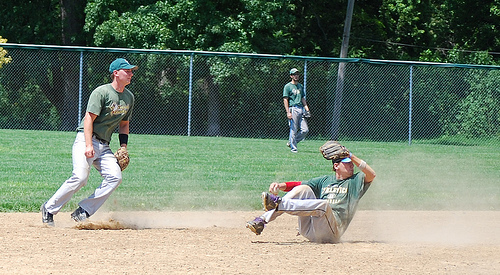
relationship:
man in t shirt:
[42, 57, 139, 225] [77, 85, 136, 139]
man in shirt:
[282, 68, 312, 152] [281, 82, 308, 108]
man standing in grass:
[282, 68, 312, 152] [1, 126, 500, 210]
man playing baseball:
[282, 68, 312, 152] [4, 5, 498, 273]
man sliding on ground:
[246, 142, 378, 246] [3, 206, 500, 274]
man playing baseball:
[246, 142, 378, 246] [4, 5, 498, 273]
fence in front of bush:
[1, 42, 500, 151] [410, 38, 500, 149]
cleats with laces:
[244, 216, 267, 234] [254, 214, 264, 226]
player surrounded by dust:
[246, 142, 378, 246] [367, 155, 499, 251]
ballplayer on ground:
[246, 142, 378, 246] [3, 206, 500, 274]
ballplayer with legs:
[246, 142, 378, 246] [247, 183, 333, 234]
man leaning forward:
[42, 57, 139, 225] [118, 60, 141, 238]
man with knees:
[42, 57, 139, 225] [69, 165, 129, 187]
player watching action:
[282, 68, 312, 152] [39, 58, 377, 245]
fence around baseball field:
[1, 42, 500, 151] [2, 125, 498, 273]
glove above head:
[317, 140, 351, 162] [332, 155, 357, 182]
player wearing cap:
[282, 68, 312, 152] [288, 66, 302, 74]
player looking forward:
[282, 68, 312, 152] [118, 60, 141, 238]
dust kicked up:
[367, 155, 499, 251] [329, 6, 481, 42]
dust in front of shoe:
[78, 213, 143, 233] [71, 207, 92, 224]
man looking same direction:
[246, 142, 378, 246] [395, 47, 478, 241]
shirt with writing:
[77, 85, 136, 139] [106, 101, 133, 117]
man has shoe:
[42, 57, 139, 225] [71, 207, 92, 224]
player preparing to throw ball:
[246, 142, 378, 246] [268, 182, 282, 196]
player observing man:
[282, 68, 312, 152] [246, 142, 378, 246]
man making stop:
[246, 142, 378, 246] [30, 57, 138, 227]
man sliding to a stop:
[42, 57, 139, 225] [30, 172, 132, 221]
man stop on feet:
[42, 57, 139, 225] [37, 200, 116, 231]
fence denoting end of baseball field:
[1, 42, 500, 151] [2, 125, 498, 273]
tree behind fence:
[86, 2, 305, 137] [1, 42, 500, 151]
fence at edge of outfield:
[1, 42, 500, 151] [2, 124, 498, 150]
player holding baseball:
[246, 142, 378, 246] [4, 5, 498, 273]